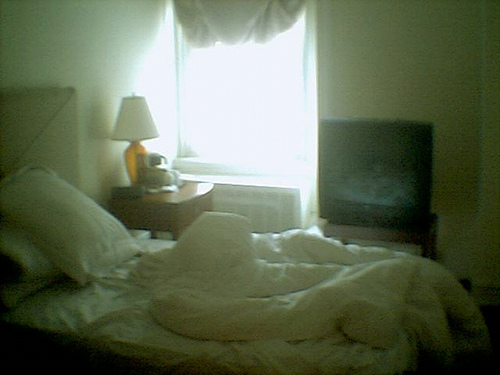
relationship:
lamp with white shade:
[110, 94, 158, 189] [110, 91, 161, 144]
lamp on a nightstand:
[110, 94, 158, 189] [108, 183, 214, 242]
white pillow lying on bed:
[5, 167, 145, 282] [1, 223, 424, 374]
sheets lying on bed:
[14, 238, 415, 375] [1, 223, 424, 374]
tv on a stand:
[313, 116, 434, 228] [313, 214, 444, 265]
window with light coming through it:
[169, 0, 319, 197] [169, 37, 306, 166]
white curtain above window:
[172, 1, 319, 49] [169, 0, 319, 197]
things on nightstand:
[128, 151, 182, 193] [105, 177, 220, 240]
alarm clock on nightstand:
[108, 183, 148, 201] [105, 177, 220, 240]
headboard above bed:
[0, 87, 95, 227] [1, 223, 424, 374]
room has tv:
[0, 0, 490, 371] [313, 116, 434, 228]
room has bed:
[0, 0, 490, 371] [1, 223, 424, 374]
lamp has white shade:
[110, 94, 158, 189] [110, 91, 161, 144]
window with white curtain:
[169, 0, 319, 197] [172, 1, 319, 49]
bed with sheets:
[1, 223, 424, 374] [14, 238, 415, 375]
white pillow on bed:
[5, 167, 145, 282] [1, 223, 424, 374]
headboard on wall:
[0, 87, 95, 227] [1, 2, 171, 243]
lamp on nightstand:
[110, 94, 158, 189] [105, 177, 220, 240]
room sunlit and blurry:
[0, 0, 490, 371] [141, 29, 343, 92]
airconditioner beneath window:
[178, 173, 316, 236] [169, 0, 319, 197]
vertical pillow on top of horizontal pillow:
[5, 167, 145, 282] [0, 212, 139, 289]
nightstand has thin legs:
[105, 177, 220, 240] [148, 227, 184, 245]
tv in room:
[313, 116, 434, 228] [0, 0, 490, 371]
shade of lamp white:
[110, 91, 161, 144] [124, 108, 146, 135]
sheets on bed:
[14, 238, 415, 375] [1, 223, 424, 374]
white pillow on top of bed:
[5, 167, 145, 282] [1, 223, 424, 374]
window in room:
[169, 0, 319, 197] [0, 0, 490, 371]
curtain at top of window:
[172, 1, 319, 49] [169, 0, 319, 197]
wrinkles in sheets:
[62, 289, 139, 333] [1, 223, 424, 374]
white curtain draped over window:
[172, 1, 319, 49] [169, 0, 319, 197]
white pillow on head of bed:
[5, 167, 145, 282] [1, 223, 424, 374]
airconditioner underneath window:
[178, 173, 316, 236] [169, 0, 319, 197]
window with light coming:
[169, 0, 319, 183] [169, 0, 319, 197]